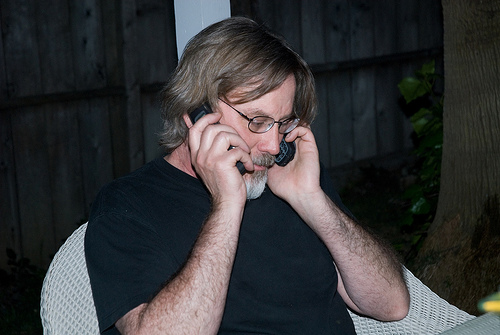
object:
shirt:
[84, 154, 355, 335]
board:
[325, 3, 435, 181]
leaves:
[397, 58, 442, 178]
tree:
[419, 4, 500, 283]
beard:
[243, 153, 277, 200]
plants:
[393, 49, 448, 225]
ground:
[412, 215, 474, 276]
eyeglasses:
[216, 96, 301, 134]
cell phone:
[187, 106, 208, 124]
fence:
[51, 44, 126, 142]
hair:
[382, 249, 399, 264]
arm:
[290, 192, 411, 322]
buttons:
[280, 149, 290, 156]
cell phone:
[274, 137, 295, 167]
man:
[84, 16, 408, 335]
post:
[172, 0, 233, 58]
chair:
[38, 221, 99, 335]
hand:
[187, 112, 255, 197]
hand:
[267, 123, 321, 198]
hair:
[154, 15, 321, 149]